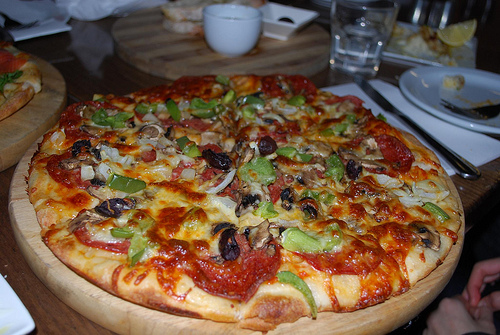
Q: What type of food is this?
A: Pizza.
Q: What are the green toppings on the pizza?
A: Peppers.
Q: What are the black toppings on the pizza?
A: Olives.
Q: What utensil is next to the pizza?
A: Knife.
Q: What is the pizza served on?
A: Serving board.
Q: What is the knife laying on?
A: A napkin.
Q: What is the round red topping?
A: Pepperoni.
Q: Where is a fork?
A: On white plate.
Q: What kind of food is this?
A: Pizza.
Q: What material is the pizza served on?
A: Wood.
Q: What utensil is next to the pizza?
A: Knife.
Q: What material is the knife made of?
A: Metal.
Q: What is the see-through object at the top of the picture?
A: Drinking glass.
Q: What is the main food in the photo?
A: Pizza.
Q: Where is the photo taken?
A: In a restaurant.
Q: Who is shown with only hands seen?
A: A person in the right corner.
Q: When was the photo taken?
A: Dinner or lunch time.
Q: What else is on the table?
A: Cups, plates, silverware, napkins.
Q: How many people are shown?
A: One.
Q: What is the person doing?
A: Sitting at a table.